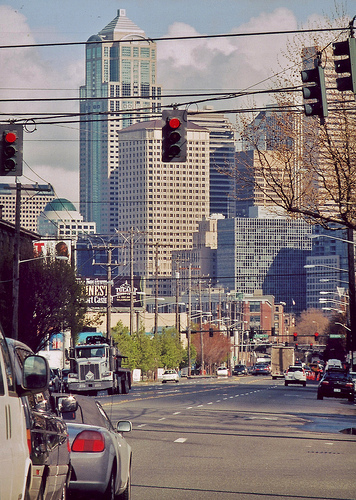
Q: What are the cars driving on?
A: The road.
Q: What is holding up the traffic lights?
A: Black wires.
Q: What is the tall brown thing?
A: A building?.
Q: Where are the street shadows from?
A: Trees aligned on sidewalk.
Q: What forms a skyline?
A: Cluster of major buildings.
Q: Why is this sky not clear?
A: There are white puffy clouds in the background.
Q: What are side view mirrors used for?
A: Viewing surrounding vehicles.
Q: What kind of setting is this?
A: Urban.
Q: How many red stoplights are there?
A: 6.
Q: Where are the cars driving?
A: Road.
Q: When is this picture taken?
A: Daytime.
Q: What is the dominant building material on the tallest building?
A: Glass.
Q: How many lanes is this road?
A: 2.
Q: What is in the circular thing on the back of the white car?
A: Spare Tire.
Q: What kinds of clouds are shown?
A: Cumulus.